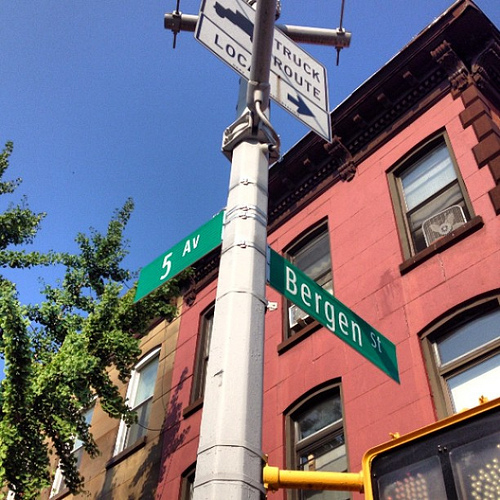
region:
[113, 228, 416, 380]
two green and white street signs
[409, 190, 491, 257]
fan in the window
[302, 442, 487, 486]
street light is yellow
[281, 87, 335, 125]
black arrow on sign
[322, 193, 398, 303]
building is red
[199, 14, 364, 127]
black and white street sign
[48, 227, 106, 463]
tree in front of building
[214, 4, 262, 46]
picture of truck on the sign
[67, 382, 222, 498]
tree shadow on the building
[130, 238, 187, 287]
5 on the street sign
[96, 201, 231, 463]
a sign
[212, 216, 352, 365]
a sign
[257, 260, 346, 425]
a sign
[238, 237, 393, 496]
a sign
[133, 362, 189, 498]
the tree's shadow on the building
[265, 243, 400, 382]
the Bergen ST sign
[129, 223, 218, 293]
the 5 Av street sign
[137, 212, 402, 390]
the two street signs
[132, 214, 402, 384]
the green street signs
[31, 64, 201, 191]
the clear blue sky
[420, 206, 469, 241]
the fan in the window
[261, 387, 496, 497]
the yellow cross walk sign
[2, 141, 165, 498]
the tall green tree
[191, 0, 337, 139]
the white sign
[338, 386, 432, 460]
the wall is red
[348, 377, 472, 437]
the wall is red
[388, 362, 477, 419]
the wall is red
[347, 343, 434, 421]
the wall is red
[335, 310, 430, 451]
the wall is red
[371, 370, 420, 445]
the wall is red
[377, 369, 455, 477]
the wall is red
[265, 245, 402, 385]
green street name sign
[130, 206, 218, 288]
green street name sign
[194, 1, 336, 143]
white traffic informational sign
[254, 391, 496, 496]
electronic do not walk sign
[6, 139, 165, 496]
a large green tree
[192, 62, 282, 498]
a tall metal pole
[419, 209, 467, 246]
a large window fan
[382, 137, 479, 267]
a building window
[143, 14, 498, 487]
a tall pink building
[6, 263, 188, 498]
a tall tan building